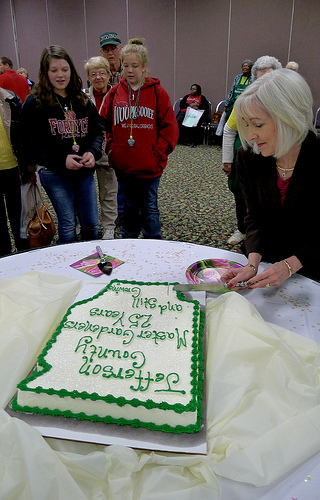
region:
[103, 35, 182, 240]
Girl in red sweatshirt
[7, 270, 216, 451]
A green and white cake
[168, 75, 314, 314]
Woman holding a knife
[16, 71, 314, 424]
Woman cutting a cake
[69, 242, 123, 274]
A pie server on a napkin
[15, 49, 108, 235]
Girl in a black sweatshirt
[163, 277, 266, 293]
Knife above a cake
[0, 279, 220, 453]
Cake with writing on it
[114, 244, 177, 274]
Confetti on the table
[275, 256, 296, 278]
Gold bracelet on wrist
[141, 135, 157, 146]
the shirt is red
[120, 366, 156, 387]
the frosting is green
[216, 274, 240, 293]
she is cutting with the knife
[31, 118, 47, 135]
the shirt is black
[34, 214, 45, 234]
the purse is brown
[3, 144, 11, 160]
the shirt is yellow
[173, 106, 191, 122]
the lady is sitting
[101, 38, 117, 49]
he is wearing a hat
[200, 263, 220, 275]
the plate is colorful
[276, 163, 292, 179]
she is wearing a necklace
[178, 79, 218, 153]
A WOMAN SITTING IN CHAIR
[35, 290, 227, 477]
A CAKE ON TOP OF A TABLE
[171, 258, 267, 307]
a person holding a knife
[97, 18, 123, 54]
a man wearing a green hat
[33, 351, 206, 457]
green piping decorating the cake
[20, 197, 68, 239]
a person carrying a brown bag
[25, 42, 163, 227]
people standing around the table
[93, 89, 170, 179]
girl wearing a red sweatshirt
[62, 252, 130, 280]
serving knife laying on top of napkin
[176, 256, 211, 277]
paper plate sitting on top of table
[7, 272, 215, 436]
Cake on the table.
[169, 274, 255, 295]
Knife in the hands.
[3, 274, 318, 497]
White table cloth on the table.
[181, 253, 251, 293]
Paper plate on the table.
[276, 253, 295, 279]
Bracelet on the wrist.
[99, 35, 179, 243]
Girl in a red sweatshirt.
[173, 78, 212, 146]
Woman sitting in the chair.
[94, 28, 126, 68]
hat on the head.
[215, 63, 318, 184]
Necklace on the woman.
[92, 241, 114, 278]
Serving utensil on the napkin.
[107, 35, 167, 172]
a girl in a red shirt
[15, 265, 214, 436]
a green and white cake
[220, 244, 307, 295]
a woman's hands with a knife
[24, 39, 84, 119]
a girl with brown hair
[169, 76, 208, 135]
a woman sitting in a chair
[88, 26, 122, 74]
a man with a green cap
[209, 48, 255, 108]
a woman with a geen shirt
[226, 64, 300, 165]
a smiling woman with gray hair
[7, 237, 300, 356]
a table with some food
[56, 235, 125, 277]
a pink and gray napkin